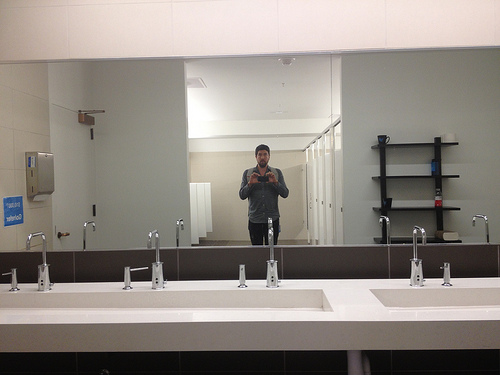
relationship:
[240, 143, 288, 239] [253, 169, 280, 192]
man holding camera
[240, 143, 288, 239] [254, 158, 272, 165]
man has beard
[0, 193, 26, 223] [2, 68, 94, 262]
sign on wall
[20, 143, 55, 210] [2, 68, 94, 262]
napkins on wall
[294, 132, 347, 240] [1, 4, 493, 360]
stalls in bathroom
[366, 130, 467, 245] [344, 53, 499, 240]
shef against wall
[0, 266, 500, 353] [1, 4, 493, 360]
sink in bathroom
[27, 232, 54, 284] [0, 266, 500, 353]
faucet on sink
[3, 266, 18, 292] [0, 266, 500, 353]
soap on sink